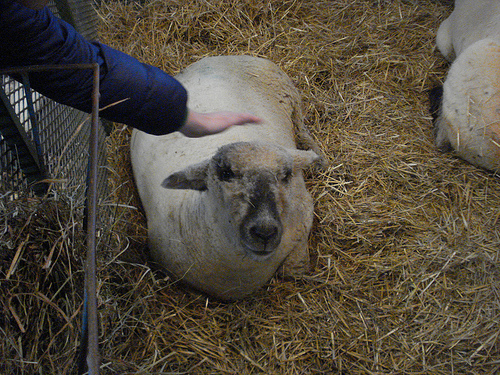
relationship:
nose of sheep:
[251, 218, 277, 242] [129, 54, 328, 302]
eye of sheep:
[219, 163, 238, 188] [129, 54, 328, 302]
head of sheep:
[162, 141, 319, 262] [129, 54, 328, 302]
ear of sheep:
[282, 147, 324, 176] [129, 54, 328, 302]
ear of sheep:
[162, 155, 208, 199] [129, 54, 328, 302]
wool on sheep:
[124, 81, 353, 300] [129, 54, 328, 302]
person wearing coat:
[0, 0, 265, 138] [6, 0, 191, 136]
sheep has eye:
[129, 54, 328, 302] [278, 170, 290, 183]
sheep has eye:
[129, 54, 328, 302] [278, 167, 298, 189]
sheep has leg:
[129, 54, 328, 302] [277, 243, 314, 285]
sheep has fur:
[129, 54, 328, 302] [131, 55, 328, 303]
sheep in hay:
[129, 54, 328, 302] [105, 27, 498, 374]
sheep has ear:
[129, 54, 328, 302] [157, 160, 213, 197]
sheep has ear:
[129, 54, 328, 302] [167, 165, 213, 190]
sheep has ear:
[129, 54, 328, 302] [290, 147, 323, 168]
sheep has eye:
[141, 23, 310, 263] [218, 158, 240, 180]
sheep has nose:
[129, 54, 328, 302] [236, 205, 287, 247]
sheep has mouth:
[129, 54, 328, 302] [248, 241, 275, 262]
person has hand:
[0, 0, 265, 138] [185, 104, 260, 133]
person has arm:
[2, 4, 263, 222] [2, 3, 187, 142]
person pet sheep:
[0, 0, 265, 138] [129, 54, 328, 302]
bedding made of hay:
[57, 12, 489, 366] [105, 27, 498, 374]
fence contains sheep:
[2, 2, 118, 374] [129, 54, 328, 302]